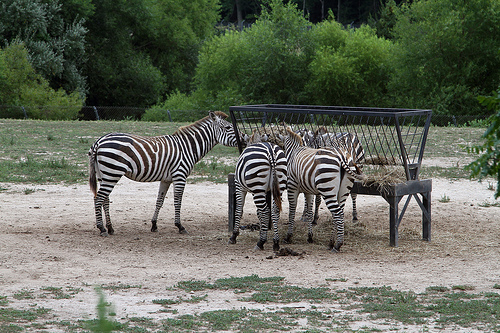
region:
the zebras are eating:
[48, 52, 475, 304]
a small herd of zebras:
[38, 29, 497, 284]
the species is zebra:
[37, 58, 497, 307]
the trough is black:
[59, 44, 477, 284]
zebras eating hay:
[53, 48, 480, 286]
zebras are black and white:
[68, 24, 493, 282]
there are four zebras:
[62, 33, 477, 298]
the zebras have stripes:
[56, 27, 484, 332]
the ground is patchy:
[35, 63, 480, 331]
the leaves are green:
[115, 18, 354, 83]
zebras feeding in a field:
[79, 87, 459, 264]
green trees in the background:
[16, 4, 486, 99]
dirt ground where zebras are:
[4, 197, 87, 277]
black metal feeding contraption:
[237, 95, 447, 131]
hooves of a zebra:
[87, 217, 200, 240]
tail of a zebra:
[86, 146, 99, 197]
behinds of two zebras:
[239, 138, 372, 207]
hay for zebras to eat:
[362, 162, 412, 196]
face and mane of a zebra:
[175, 109, 247, 149]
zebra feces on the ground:
[264, 239, 309, 271]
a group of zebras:
[88, 91, 374, 253]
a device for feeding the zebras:
[218, 85, 421, 174]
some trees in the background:
[104, 16, 411, 101]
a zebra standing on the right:
[77, 115, 249, 210]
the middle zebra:
[238, 129, 298, 256]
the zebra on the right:
[272, 120, 372, 268]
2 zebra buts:
[242, 132, 374, 204]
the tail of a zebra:
[83, 140, 115, 217]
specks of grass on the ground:
[113, 275, 328, 324]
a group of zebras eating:
[86, 71, 445, 258]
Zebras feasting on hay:
[84, 104, 360, 238]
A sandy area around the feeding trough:
[37, 185, 313, 271]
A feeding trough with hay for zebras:
[223, 107, 465, 207]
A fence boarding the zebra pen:
[35, 95, 148, 122]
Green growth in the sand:
[225, 276, 372, 328]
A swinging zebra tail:
[296, 137, 399, 199]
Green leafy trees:
[203, 7, 389, 108]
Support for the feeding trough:
[377, 166, 450, 246]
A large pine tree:
[12, 6, 88, 73]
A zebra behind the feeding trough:
[285, 118, 378, 168]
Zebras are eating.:
[57, 90, 414, 263]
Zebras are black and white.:
[81, 91, 370, 260]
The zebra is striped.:
[77, 98, 213, 218]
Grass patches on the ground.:
[35, 242, 487, 331]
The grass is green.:
[8, 120, 236, 177]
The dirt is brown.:
[35, 190, 365, 281]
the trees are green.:
[44, 32, 420, 102]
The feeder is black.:
[227, 90, 456, 250]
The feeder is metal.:
[216, 82, 463, 242]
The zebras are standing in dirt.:
[60, 98, 370, 272]